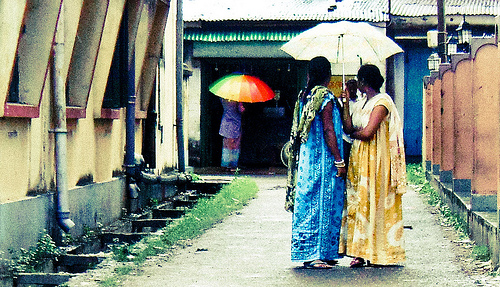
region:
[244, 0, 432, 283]
Woman's standing with umbrella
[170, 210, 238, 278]
Green color grass with dirt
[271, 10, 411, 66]
White color umbrella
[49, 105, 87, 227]
Water outlet pipe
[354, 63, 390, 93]
Head of the woman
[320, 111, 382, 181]
Hands of the woman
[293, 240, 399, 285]
Peoples wearing pair of chapples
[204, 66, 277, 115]
Multi colored umbrella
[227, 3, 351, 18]
Metal sheet roof of the building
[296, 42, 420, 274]
a group of indian women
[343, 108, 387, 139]
the arm of a woman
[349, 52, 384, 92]
the head of a woman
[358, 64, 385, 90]
the hair of a woman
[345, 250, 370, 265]
the feet of a woman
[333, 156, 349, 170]
the bracelet of a woman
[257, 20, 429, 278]
two women with an umbrella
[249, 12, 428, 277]
two women with an umbrella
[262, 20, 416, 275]
two women with an umbrella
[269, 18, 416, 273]
two women with an umbrella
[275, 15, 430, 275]
two women with an umbrella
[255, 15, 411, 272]
two women with an umbrella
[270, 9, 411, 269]
two women with an umbrella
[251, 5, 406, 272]
two women with an umbrella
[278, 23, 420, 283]
two women with an umbrella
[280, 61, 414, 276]
two woman on street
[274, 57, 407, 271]
two woman on street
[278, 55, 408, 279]
two woman on street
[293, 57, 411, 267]
two woman on street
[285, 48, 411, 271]
two woman on street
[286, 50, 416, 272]
two woman on street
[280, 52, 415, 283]
two woman on street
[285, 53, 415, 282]
two woman on street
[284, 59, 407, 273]
two woman on street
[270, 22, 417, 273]
two woman on street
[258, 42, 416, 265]
two woman on street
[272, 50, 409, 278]
two woman on street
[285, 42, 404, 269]
two woman on street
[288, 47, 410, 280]
two woman on street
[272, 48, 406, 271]
two woman on street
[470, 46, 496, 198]
tan column by the walkway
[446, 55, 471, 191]
tan column by the walkway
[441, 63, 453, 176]
tan column by the walkway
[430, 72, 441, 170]
tan column by the walkway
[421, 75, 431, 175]
tan column by the walkway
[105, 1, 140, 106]
tan column by the walkway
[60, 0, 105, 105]
tan column by the walkway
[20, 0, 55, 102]
tan column by the walkway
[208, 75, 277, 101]
the umbrella is colorful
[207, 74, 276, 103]
the umbrella is opened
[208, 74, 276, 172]
the woman is carrying an umbrella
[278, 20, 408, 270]
the women under the umbrella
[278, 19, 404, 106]
the umbrella is white